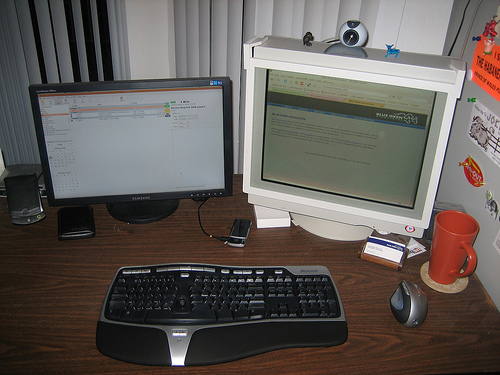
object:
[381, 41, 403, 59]
horse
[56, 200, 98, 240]
wallet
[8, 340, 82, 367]
desk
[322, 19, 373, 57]
web cam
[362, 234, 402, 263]
business card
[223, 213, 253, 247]
cellphone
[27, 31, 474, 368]
computer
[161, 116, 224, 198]
screen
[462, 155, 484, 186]
stickers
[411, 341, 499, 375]
desk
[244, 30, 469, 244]
computer monitor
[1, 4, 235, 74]
blinds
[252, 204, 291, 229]
pad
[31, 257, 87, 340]
desk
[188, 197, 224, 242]
cord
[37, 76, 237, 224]
black monitor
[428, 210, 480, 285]
coffee mug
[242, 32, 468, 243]
monitor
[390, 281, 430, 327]
computer mouse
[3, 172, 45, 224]
gray speaker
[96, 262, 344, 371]
keyboard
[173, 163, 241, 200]
screen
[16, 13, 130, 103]
window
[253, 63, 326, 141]
screen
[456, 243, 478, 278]
cup handle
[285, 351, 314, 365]
desk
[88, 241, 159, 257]
desk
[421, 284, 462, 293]
coaster